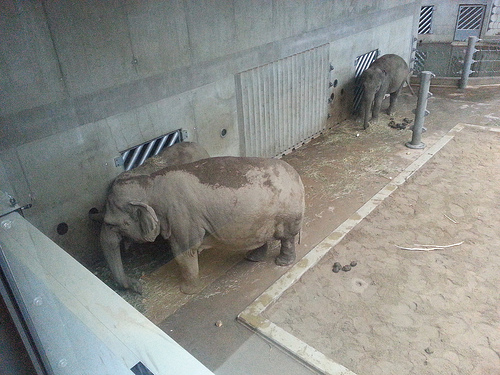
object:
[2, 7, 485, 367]
pen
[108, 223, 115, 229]
eye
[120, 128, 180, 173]
bar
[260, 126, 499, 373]
dirt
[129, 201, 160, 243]
ear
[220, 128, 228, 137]
hole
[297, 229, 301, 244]
tail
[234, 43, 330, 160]
door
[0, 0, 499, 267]
wall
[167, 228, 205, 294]
legs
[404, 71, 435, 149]
pole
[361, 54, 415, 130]
elephant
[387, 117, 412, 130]
poop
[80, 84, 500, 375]
floor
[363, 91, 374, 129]
trunk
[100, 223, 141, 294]
trunk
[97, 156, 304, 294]
elephant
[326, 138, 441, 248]
concrete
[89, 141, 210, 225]
elephant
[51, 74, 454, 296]
cage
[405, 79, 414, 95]
tail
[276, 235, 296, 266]
legs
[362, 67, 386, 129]
head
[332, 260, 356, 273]
dung